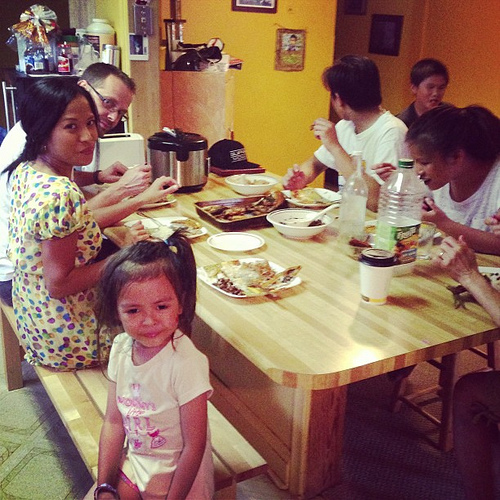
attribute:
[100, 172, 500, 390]
table — here, wooden, full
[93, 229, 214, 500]
girl — here, little, young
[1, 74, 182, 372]
lady — here, sitting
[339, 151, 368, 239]
bottle — here, glass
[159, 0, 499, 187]
wall — here, cream, yellow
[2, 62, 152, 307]
man — sitting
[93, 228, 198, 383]
hair — pony tail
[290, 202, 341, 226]
spoon — white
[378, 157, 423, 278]
bottle — plastic, large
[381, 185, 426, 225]
surface — ribbed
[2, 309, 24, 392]
leg — wooden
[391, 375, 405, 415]
leg — wooden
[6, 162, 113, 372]
dress — polka dot, multicolored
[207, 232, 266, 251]
plate — empty, white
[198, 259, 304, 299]
plate — square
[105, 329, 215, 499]
shirt — pink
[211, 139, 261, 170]
cap — black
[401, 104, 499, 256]
woman — eating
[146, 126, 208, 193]
rice cooker — metal, black, silver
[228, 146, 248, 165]
design — white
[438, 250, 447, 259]
ring — gold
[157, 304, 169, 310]
eye — dark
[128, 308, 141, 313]
eye — dark